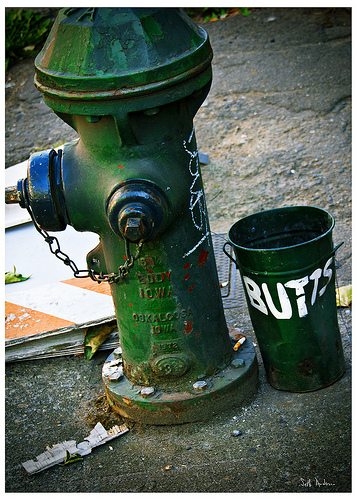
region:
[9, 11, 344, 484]
Green fire hydrant in Iowa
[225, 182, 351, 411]
Trash can next to green fire hyrant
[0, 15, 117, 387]
Construction stand on ground next to fire hydrant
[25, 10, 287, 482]
Fire hydrant has Iowa written on the front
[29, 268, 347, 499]
The ground is comprised of cement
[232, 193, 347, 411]
Green garbage pall has Butts written on it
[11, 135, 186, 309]
A chain is draping from the fire hydrant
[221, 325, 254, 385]
Cigarette butt on the base of a fire hydrant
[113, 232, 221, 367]
Reddish brown rust marks on the fire hydrant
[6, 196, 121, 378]
construction stand has white and orange stripes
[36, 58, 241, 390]
The fire hydrant is green.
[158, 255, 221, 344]
The fire hydrant has red spots.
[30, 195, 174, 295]
The chain hangs from the fire hydrant.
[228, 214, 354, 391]
The green bucket is next to the fire hydrant.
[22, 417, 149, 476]
A piece of paper on the ground.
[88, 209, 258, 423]
The fire hydrant is old and rusty.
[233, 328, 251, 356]
A cigarette bud lays on the fire hydrant.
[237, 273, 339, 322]
The writing on the bucket is white.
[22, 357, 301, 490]
The sidewalk is very old looking.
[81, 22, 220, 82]
The paint on the fire hydrant is peeling off.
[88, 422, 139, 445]
white object on ground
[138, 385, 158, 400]
large bolt on fire hydrant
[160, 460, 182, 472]
small white pebble on ground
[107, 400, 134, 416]
rust spot on fire hydrant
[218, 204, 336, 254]
top of green bucket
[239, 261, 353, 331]
white words on green bucket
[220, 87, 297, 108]
large crack on asphalt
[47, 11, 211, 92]
large green and blue top of hydrant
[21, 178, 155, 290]
large chain on hdyrant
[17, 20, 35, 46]
green bush in background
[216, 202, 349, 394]
can with words butts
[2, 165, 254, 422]
green fire hydrant on street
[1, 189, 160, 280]
chain on fire hydrant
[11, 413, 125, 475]
piece of trash on ground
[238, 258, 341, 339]
butts written in white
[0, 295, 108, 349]
orange and white road sign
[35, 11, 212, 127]
octagonal shaped top of hydrant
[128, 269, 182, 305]
iowa words on hydrant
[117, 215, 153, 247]
bolt on fire hydrant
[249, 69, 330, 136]
asphalt on road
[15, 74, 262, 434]
dark green fire hydrant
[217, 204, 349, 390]
bucket for cigarette butts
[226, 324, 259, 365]
cigarette butt on fire hydrant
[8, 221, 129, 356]
orange and white caution signs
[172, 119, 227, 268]
chalk markings on fire hydrant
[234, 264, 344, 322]
"butts" painted in white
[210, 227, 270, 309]
man hole cover behind bucket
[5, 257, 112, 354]
leaves laying on signs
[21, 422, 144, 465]
garbage laying on the pavement